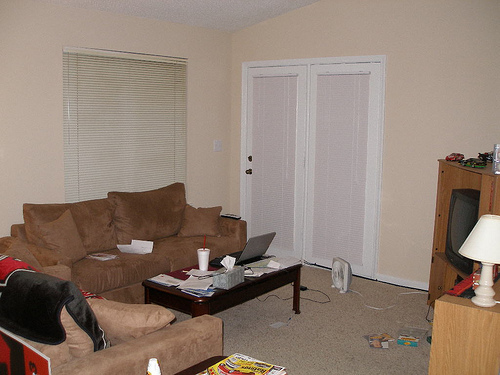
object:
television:
[445, 188, 480, 276]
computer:
[209, 231, 275, 267]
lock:
[248, 156, 252, 162]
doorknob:
[246, 169, 253, 175]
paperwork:
[116, 239, 153, 255]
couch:
[0, 265, 225, 375]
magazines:
[197, 353, 287, 375]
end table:
[174, 355, 285, 374]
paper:
[116, 239, 153, 255]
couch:
[0, 182, 247, 305]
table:
[427, 277, 500, 374]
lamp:
[458, 215, 499, 308]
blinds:
[63, 51, 187, 203]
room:
[0, 4, 497, 369]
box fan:
[331, 257, 353, 294]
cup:
[197, 248, 210, 271]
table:
[140, 254, 303, 319]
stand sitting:
[426, 159, 500, 308]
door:
[238, 64, 307, 263]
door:
[303, 63, 381, 279]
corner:
[375, 17, 484, 373]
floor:
[291, 291, 389, 370]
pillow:
[177, 204, 222, 238]